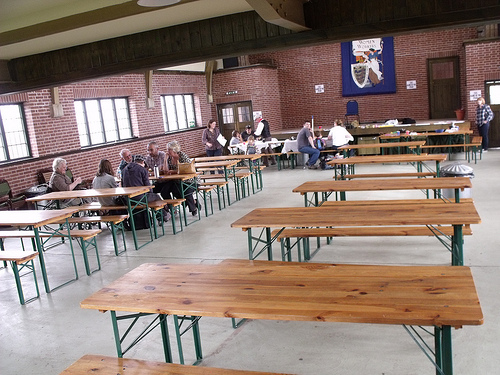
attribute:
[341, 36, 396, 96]
sign — green, white, for parking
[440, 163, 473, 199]
can — silver, for trash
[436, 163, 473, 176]
lid — silver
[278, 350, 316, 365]
spot — dark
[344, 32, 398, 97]
object — blue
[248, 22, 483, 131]
wall — brick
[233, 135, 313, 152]
tablecloth — white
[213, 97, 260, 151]
doors — wooden, double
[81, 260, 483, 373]
table — wooden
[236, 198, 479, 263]
table — wooden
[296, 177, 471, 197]
table — wooden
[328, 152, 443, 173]
table — wooden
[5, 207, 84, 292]
table — wooden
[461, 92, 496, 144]
shirt — plaid, long sleeve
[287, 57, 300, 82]
bricks — red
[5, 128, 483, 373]
table — wooden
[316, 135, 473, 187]
chair — blue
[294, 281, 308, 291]
spot — dark brown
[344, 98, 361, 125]
chair — blue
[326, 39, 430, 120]
sign — green, white